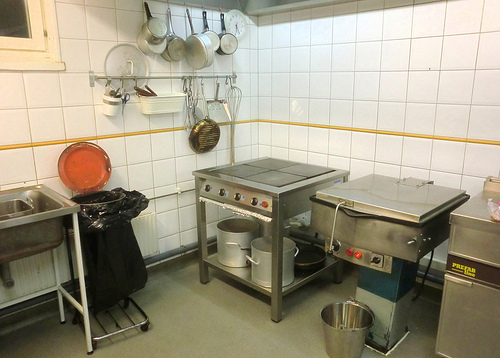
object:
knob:
[371, 256, 381, 264]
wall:
[0, 0, 500, 308]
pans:
[160, 8, 189, 63]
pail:
[318, 296, 375, 358]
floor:
[165, 323, 302, 358]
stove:
[308, 174, 471, 356]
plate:
[57, 141, 111, 194]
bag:
[65, 186, 150, 317]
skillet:
[188, 84, 221, 154]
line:
[259, 119, 499, 147]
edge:
[1, 34, 34, 41]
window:
[0, 0, 33, 40]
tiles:
[331, 44, 356, 72]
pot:
[185, 9, 215, 70]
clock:
[224, 9, 247, 38]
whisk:
[224, 86, 243, 166]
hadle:
[144, 2, 154, 19]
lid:
[104, 44, 149, 95]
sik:
[0, 183, 96, 355]